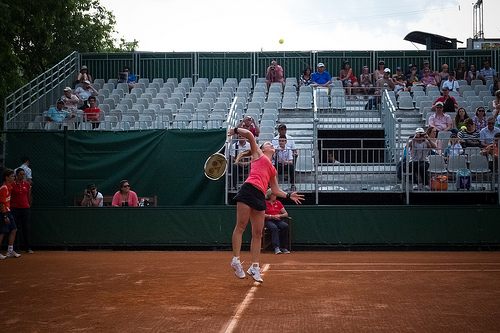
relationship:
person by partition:
[259, 185, 301, 252] [18, 206, 482, 260]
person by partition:
[204, 115, 306, 290] [18, 206, 482, 260]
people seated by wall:
[80, 180, 107, 209] [4, 131, 225, 213]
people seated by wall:
[109, 177, 140, 206] [4, 131, 225, 213]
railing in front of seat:
[228, 140, 495, 204] [298, 92, 312, 106]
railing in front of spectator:
[228, 140, 495, 204] [273, 137, 295, 180]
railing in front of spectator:
[228, 140, 495, 204] [268, 125, 297, 162]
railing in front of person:
[228, 140, 495, 204] [409, 127, 437, 191]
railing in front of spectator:
[228, 140, 495, 204] [442, 123, 467, 172]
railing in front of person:
[228, 140, 495, 204] [428, 100, 458, 134]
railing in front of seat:
[228, 140, 495, 204] [330, 92, 344, 109]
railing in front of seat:
[228, 140, 495, 204] [258, 129, 272, 142]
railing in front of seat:
[228, 140, 495, 204] [268, 91, 278, 103]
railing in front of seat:
[228, 140, 495, 204] [398, 92, 412, 107]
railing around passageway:
[222, 140, 495, 203] [316, 122, 386, 172]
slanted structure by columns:
[404, 28, 461, 52] [462, 3, 478, 41]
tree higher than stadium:
[2, 4, 125, 70] [11, 11, 498, 323]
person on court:
[204, 127, 306, 283] [19, 239, 484, 331]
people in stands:
[265, 56, 496, 91] [37, 45, 484, 234]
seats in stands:
[113, 82, 300, 106] [6, 45, 480, 247]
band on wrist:
[285, 192, 290, 199] [285, 190, 292, 200]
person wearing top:
[204, 127, 306, 283] [238, 147, 285, 191]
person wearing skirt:
[204, 127, 306, 283] [236, 180, 268, 217]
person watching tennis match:
[72, 80, 96, 108] [18, 148, 488, 318]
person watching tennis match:
[74, 61, 93, 86] [5, 167, 485, 317]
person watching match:
[266, 58, 283, 84] [9, 164, 489, 323]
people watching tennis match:
[111, 179, 138, 207] [1, 174, 494, 305]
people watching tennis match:
[80, 182, 103, 206] [38, 85, 495, 332]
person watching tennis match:
[407, 126, 435, 191] [5, 167, 485, 317]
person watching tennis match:
[406, 94, 455, 134] [23, 159, 482, 304]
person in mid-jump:
[204, 127, 306, 283] [226, 265, 262, 296]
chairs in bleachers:
[121, 74, 275, 121] [38, 69, 490, 182]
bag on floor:
[429, 172, 448, 189] [414, 189, 457, 192]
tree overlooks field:
[0, 0, 139, 70] [7, 282, 472, 327]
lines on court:
[220, 260, 497, 331] [29, 255, 497, 324]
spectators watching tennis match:
[394, 54, 499, 185] [4, 128, 500, 333]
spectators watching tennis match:
[259, 55, 401, 100] [4, 128, 500, 333]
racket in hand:
[204, 130, 234, 181] [227, 125, 237, 139]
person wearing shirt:
[9, 163, 34, 263] [21, 177, 33, 209]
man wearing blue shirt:
[306, 60, 333, 87] [306, 68, 333, 83]